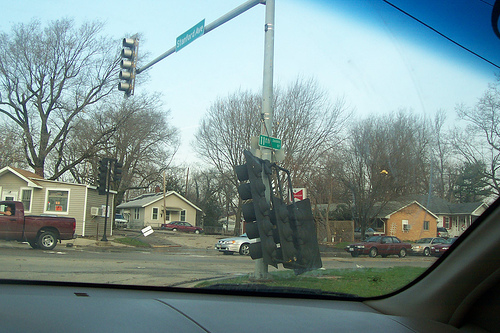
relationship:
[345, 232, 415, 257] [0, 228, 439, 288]
car in road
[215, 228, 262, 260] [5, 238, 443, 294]
car on road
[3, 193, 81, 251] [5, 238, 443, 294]
truck on road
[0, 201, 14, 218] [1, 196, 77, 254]
driver in truck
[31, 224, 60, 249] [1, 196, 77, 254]
tire on truck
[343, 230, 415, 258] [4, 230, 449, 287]
car on road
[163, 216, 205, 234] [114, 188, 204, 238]
car in front of house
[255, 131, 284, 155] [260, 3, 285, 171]
road sign on post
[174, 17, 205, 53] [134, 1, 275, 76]
road sign on post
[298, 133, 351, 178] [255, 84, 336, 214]
branch on tree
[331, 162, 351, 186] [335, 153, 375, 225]
branch on tree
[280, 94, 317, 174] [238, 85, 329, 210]
branch on tree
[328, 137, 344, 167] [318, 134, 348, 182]
branch on tree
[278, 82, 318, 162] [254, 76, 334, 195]
branch on tree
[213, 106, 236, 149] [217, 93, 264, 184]
branch on tree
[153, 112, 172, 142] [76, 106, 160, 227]
branch on tree